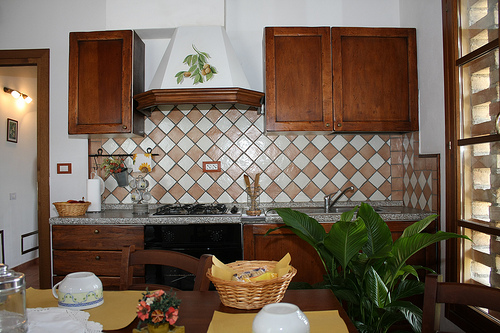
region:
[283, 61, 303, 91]
the cabinets are brown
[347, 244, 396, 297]
the plant is green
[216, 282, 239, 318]
the basket is on the table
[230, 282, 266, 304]
the basket is woven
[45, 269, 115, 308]
the bowl is upside down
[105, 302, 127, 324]
the place mat is yellow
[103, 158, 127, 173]
the flower is red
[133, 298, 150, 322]
the flower is pink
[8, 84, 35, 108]
the lights are on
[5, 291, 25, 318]
the canister is clear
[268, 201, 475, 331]
leaves of a green plant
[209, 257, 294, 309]
a wicker basket on a table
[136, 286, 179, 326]
a small plastic bouquet of flowers on a table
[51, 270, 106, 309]
a cup upside down on a table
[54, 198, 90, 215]
a wicker basket on a kitchen counter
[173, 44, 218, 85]
flowers and leaves painted on a white wall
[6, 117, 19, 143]
a framed picture on a wall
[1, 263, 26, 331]
a glass jar on a table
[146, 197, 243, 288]
an oven with burners on a kitchen counter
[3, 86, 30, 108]
light fixtures on a wall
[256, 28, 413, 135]
cabinets on wall of kitchen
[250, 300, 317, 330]
bowl turned upside down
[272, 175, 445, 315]
plant in the room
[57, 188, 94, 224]
basket on counter in room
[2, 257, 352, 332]
table with items on it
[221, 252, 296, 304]
basket on the table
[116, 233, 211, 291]
chair at the table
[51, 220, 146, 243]
drawer at the counter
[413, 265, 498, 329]
chair by the plant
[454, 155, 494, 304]
window to the room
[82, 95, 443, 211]
THE TILE ON THE WALL IS BROWN AND WHITE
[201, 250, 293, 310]
THE BASKET IS ON THE TABLE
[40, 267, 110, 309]
THE CUP IS LARGE AND IS UPSIDE DOWN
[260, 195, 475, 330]
THE PEACE LILLY IS ON THE FLOOR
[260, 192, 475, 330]
THE PEACE LILLY IS VERY BIG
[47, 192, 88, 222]
THE BASKET IS ON THE COUNTER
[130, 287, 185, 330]
THE FLOWERS ARE ON THE TABLE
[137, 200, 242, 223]
THE STOVE TOP IS IN THE COUNTER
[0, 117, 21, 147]
THE PICTURE IS HANGING ON THE WALL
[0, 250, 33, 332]
THE CANISTER HAS A SILVER TOP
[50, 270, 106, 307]
a cup that is upside down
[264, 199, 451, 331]
a large green leafy plant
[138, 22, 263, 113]
an oven hood with a plant pained on it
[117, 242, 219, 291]
a wooden kitchen chair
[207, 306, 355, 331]
a light brown placemat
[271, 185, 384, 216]
a metal kitchen sink and faucet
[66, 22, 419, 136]
three brown kitchen cabinets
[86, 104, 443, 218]
kitchen backsplash with a diamond pattern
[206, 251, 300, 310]
a brown basket with a liner in it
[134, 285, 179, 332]
pink and white flowers